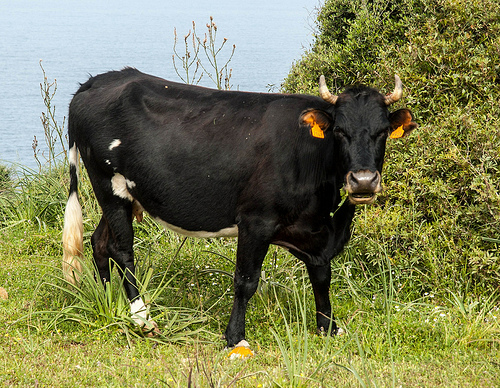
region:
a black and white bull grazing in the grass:
[63, 68, 413, 349]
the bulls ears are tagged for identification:
[298, 108, 330, 140]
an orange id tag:
[388, 126, 404, 141]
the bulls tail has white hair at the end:
[62, 119, 83, 284]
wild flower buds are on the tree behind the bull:
[170, 14, 243, 87]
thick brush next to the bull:
[415, 1, 498, 338]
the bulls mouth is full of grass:
[330, 170, 380, 216]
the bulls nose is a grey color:
[347, 172, 379, 194]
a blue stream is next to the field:
[1, 0, 171, 66]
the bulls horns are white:
[318, 75, 339, 102]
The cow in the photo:
[55, 61, 422, 353]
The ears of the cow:
[295, 103, 421, 150]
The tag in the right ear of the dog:
[309, 121, 328, 141]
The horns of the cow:
[310, 66, 402, 108]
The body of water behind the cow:
[0, 1, 312, 181]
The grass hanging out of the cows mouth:
[324, 182, 350, 221]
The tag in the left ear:
[388, 122, 404, 139]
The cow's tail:
[60, 118, 90, 297]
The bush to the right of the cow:
[276, 0, 498, 297]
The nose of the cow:
[345, 168, 379, 197]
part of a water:
[233, 17, 277, 70]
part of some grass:
[346, 326, 403, 374]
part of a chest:
[298, 207, 337, 259]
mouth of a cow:
[354, 184, 373, 205]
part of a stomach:
[181, 216, 212, 241]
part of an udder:
[133, 208, 152, 230]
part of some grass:
[399, 327, 449, 361]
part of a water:
[123, 15, 155, 36]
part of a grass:
[371, 325, 404, 362]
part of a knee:
[232, 264, 260, 300]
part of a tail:
[50, 213, 82, 254]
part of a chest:
[310, 203, 346, 269]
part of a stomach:
[185, 192, 225, 229]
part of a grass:
[364, 299, 424, 354]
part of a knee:
[229, 257, 280, 322]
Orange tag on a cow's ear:
[305, 119, 327, 138]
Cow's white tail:
[56, 194, 89, 282]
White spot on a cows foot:
[124, 297, 162, 342]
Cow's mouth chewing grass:
[327, 179, 380, 221]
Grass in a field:
[37, 258, 205, 349]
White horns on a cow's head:
[313, 72, 412, 104]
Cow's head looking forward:
[296, 72, 417, 215]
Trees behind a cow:
[301, 55, 498, 278]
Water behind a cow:
[9, 40, 191, 188]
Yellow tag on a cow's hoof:
[223, 337, 258, 360]